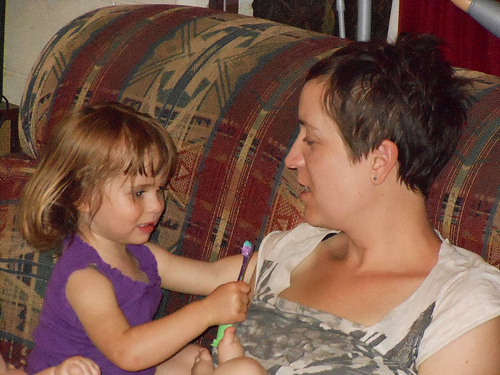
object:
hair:
[19, 102, 178, 252]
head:
[17, 100, 175, 253]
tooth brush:
[211, 240, 255, 348]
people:
[2, 32, 498, 375]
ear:
[371, 139, 399, 184]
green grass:
[280, 34, 469, 251]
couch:
[2, 3, 499, 375]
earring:
[374, 177, 377, 181]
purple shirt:
[27, 233, 162, 375]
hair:
[306, 32, 477, 200]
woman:
[212, 32, 500, 375]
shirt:
[231, 222, 500, 375]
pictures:
[235, 258, 434, 375]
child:
[17, 100, 257, 375]